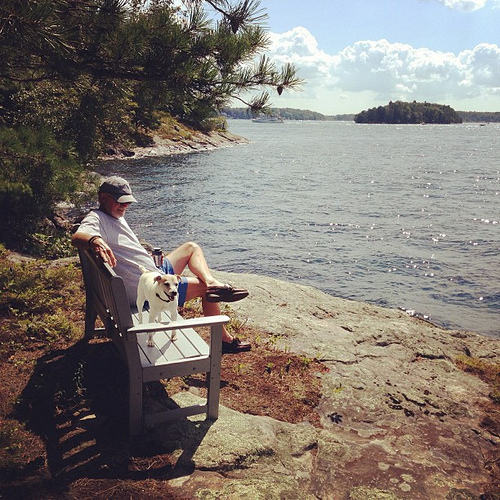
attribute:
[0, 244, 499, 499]
ground — rocky, bare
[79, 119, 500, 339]
water — deep, blue, glistening, green, clam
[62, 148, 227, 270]
harbor area — natural, uneven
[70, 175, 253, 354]
man — sockless, dressed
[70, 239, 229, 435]
bench — wooden, elderly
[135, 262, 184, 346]
dog — small, white, standing, facing forward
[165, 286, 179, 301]
muzzle — tan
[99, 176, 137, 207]
cap — baseball hat, khaki, ball cap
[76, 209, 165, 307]
t shirt — white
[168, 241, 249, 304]
leg — pale, crossed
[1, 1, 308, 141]
branch — evergreen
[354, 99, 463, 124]
island — distant, small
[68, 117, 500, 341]
lake — large, deep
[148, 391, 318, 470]
rock — wide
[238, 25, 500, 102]
cloud — large, puffy, fluffy, white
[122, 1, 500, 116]
sky — blue, porcelain blue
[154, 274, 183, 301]
face — brown